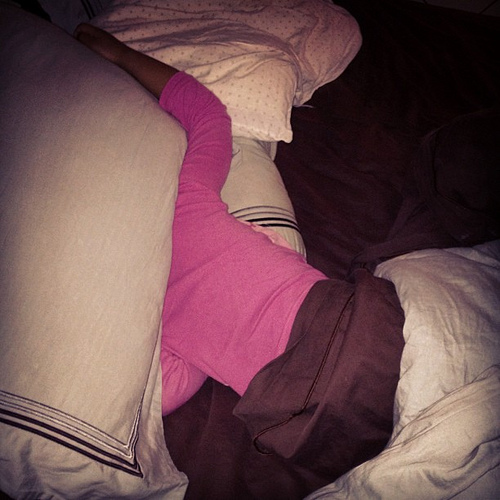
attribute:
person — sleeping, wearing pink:
[73, 22, 500, 416]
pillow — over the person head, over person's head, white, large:
[2, 5, 187, 500]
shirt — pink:
[158, 70, 324, 416]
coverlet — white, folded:
[295, 242, 498, 499]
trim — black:
[0, 406, 145, 481]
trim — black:
[247, 217, 303, 236]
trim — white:
[0, 393, 142, 462]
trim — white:
[227, 204, 294, 218]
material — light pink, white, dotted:
[93, 2, 363, 145]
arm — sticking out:
[79, 24, 232, 218]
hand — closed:
[72, 23, 126, 59]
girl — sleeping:
[72, 24, 325, 424]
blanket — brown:
[232, 1, 498, 499]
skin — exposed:
[74, 23, 176, 99]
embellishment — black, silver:
[224, 207, 303, 230]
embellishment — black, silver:
[0, 390, 146, 477]